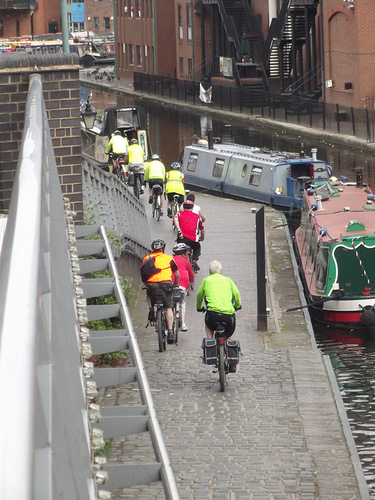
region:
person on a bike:
[197, 260, 242, 390]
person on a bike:
[140, 239, 172, 348]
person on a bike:
[166, 244, 189, 329]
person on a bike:
[171, 201, 203, 269]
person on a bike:
[166, 163, 185, 216]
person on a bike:
[144, 155, 164, 216]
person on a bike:
[103, 130, 123, 169]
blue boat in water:
[181, 141, 328, 205]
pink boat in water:
[298, 179, 373, 316]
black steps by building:
[199, 2, 334, 110]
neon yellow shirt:
[198, 272, 259, 321]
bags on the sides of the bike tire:
[191, 330, 247, 368]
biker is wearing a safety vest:
[168, 169, 186, 201]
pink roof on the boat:
[327, 194, 374, 237]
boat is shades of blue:
[166, 148, 301, 205]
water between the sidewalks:
[131, 61, 187, 197]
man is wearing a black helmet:
[150, 238, 176, 250]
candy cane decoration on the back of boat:
[344, 236, 373, 288]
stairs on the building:
[283, 71, 339, 110]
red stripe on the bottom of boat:
[327, 307, 364, 325]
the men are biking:
[141, 231, 256, 379]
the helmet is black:
[145, 226, 171, 257]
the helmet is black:
[138, 238, 169, 261]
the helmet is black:
[158, 235, 201, 266]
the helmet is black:
[169, 233, 194, 261]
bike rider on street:
[197, 261, 254, 376]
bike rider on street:
[135, 238, 173, 343]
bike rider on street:
[167, 242, 194, 289]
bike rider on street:
[166, 197, 208, 251]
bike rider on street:
[159, 160, 186, 206]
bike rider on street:
[148, 154, 166, 201]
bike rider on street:
[124, 134, 147, 188]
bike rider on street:
[104, 127, 131, 165]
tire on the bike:
[205, 345, 237, 394]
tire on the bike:
[148, 311, 168, 354]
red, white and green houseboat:
[310, 181, 374, 322]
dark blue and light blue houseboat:
[184, 135, 329, 205]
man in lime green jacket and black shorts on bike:
[195, 261, 245, 391]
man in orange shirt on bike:
[140, 240, 185, 350]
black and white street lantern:
[79, 95, 98, 134]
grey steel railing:
[6, 75, 84, 499]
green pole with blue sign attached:
[59, 1, 91, 53]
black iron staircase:
[226, 0, 273, 105]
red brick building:
[110, 0, 216, 83]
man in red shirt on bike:
[173, 200, 204, 262]